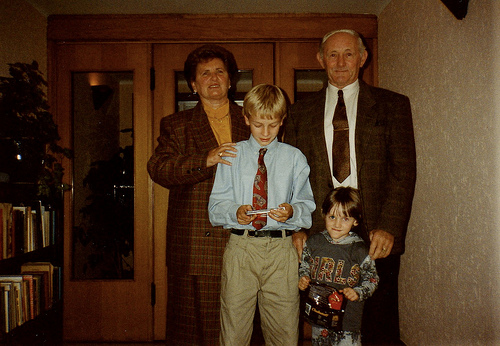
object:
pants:
[218, 227, 299, 344]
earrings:
[189, 81, 199, 96]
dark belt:
[224, 225, 301, 239]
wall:
[372, 0, 500, 346]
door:
[55, 42, 151, 344]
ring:
[381, 245, 388, 251]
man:
[283, 26, 417, 346]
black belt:
[226, 221, 298, 238]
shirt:
[206, 137, 315, 231]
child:
[295, 182, 381, 346]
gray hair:
[319, 27, 364, 57]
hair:
[243, 79, 292, 124]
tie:
[251, 148, 268, 229]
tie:
[331, 89, 351, 184]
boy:
[208, 85, 319, 345]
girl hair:
[311, 187, 360, 220]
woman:
[145, 42, 254, 346]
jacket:
[282, 85, 419, 257]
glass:
[66, 67, 137, 286]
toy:
[294, 275, 350, 332]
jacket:
[146, 97, 254, 343]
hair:
[182, 38, 241, 92]